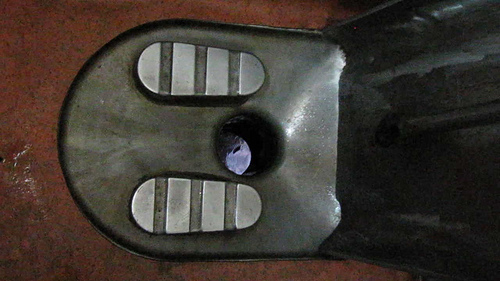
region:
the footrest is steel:
[106, 158, 306, 256]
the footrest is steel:
[119, 131, 256, 241]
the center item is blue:
[203, 122, 287, 204]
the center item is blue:
[211, 125, 311, 251]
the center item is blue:
[207, 126, 257, 191]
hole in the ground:
[207, 102, 287, 179]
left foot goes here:
[127, 175, 265, 234]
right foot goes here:
[136, 39, 268, 99]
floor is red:
[1, 0, 62, 280]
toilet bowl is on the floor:
[56, 14, 356, 261]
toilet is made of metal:
[55, 15, 342, 262]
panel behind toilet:
[330, 2, 496, 272]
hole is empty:
[210, 100, 290, 180]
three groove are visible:
[131, 27, 268, 103]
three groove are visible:
[128, 175, 260, 237]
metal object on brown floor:
[60, 10, 346, 268]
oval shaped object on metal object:
[129, 174, 263, 229]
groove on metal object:
[183, 177, 206, 234]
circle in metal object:
[211, 107, 287, 178]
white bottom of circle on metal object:
[215, 130, 254, 180]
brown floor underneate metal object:
[2, 1, 417, 280]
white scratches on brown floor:
[8, 138, 60, 237]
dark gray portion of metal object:
[326, 2, 499, 272]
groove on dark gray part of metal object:
[392, 103, 499, 138]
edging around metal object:
[231, 11, 324, 42]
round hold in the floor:
[205, 116, 302, 178]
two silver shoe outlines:
[93, 24, 295, 244]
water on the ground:
[7, 146, 58, 203]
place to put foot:
[125, 167, 282, 240]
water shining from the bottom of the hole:
[220, 138, 257, 167]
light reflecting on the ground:
[281, 98, 302, 135]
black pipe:
[391, 98, 496, 142]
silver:
[41, 23, 361, 258]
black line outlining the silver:
[53, 106, 77, 165]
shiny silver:
[323, 189, 345, 220]